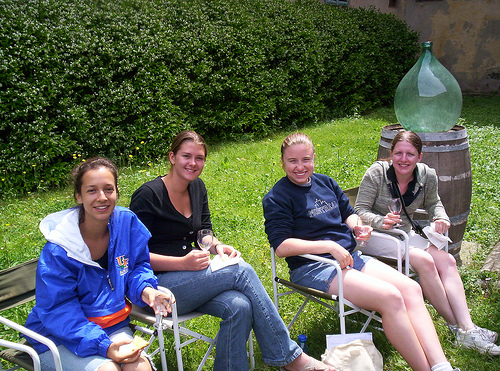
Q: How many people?
A: 4.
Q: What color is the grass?
A: Green.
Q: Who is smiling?
A: The girl.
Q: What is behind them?
A: Bushes.